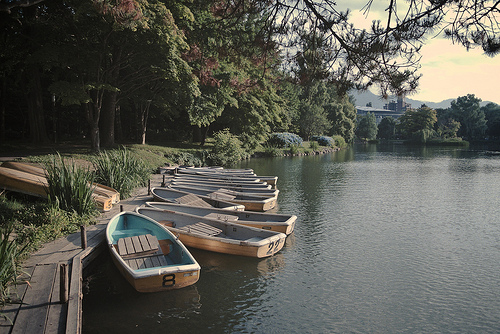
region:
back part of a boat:
[141, 267, 181, 291]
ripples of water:
[369, 231, 412, 274]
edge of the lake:
[285, 141, 330, 157]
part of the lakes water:
[383, 232, 423, 275]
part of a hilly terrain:
[422, 99, 437, 103]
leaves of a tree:
[329, 100, 339, 114]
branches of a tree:
[355, 21, 375, 33]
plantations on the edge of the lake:
[19, 211, 67, 256]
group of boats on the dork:
[173, 164, 200, 207]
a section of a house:
[383, 102, 393, 111]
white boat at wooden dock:
[107, 227, 180, 296]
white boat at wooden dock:
[166, 180, 290, 213]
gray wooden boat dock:
[26, 254, 79, 328]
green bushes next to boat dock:
[97, 149, 140, 184]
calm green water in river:
[225, 270, 499, 331]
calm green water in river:
[307, 165, 489, 245]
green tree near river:
[451, 96, 486, 141]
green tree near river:
[14, 15, 120, 144]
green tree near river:
[128, 8, 284, 125]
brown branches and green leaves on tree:
[356, 3, 491, 58]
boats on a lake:
[82, 125, 289, 332]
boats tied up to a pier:
[69, 127, 389, 332]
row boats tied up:
[47, 102, 356, 314]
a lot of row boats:
[43, 118, 363, 319]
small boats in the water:
[76, 128, 362, 305]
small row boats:
[87, 125, 290, 301]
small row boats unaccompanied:
[83, 136, 321, 281]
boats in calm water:
[64, 125, 355, 306]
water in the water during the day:
[79, 128, 306, 331]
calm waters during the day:
[293, 162, 498, 315]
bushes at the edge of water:
[300, 140, 325, 160]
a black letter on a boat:
[150, 265, 176, 285]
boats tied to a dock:
[170, 160, 215, 196]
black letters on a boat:
[265, 235, 282, 251]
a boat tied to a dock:
[101, 208, 204, 293]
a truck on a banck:
[80, 115, 106, 155]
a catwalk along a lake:
[12, 272, 107, 330]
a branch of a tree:
[310, 13, 400, 79]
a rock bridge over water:
[351, 101, 392, 141]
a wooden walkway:
[9, 172, 53, 196]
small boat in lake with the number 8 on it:
[116, 211, 191, 293]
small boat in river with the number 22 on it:
[159, 204, 304, 256]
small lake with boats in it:
[359, 157, 499, 276]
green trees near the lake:
[182, 17, 374, 141]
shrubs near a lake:
[128, 168, 188, 327]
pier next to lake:
[0, 233, 88, 331]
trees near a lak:
[437, 86, 499, 140]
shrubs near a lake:
[257, 127, 348, 154]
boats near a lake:
[155, 137, 288, 194]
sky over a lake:
[418, 53, 490, 88]